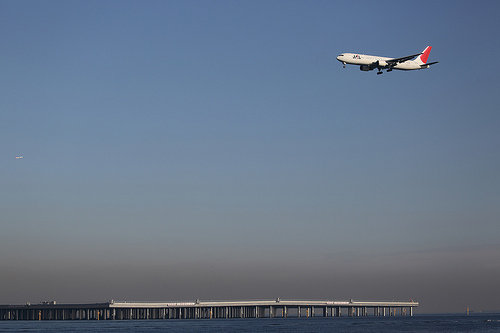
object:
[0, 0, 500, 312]
clouds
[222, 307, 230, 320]
wood post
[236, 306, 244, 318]
wood post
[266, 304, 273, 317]
wood post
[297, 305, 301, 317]
wood post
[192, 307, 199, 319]
wood post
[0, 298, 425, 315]
pier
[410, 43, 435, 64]
tail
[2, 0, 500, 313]
sky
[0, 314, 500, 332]
ocean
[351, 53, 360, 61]
logo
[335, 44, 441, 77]
plane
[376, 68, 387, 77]
landing gear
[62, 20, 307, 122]
air